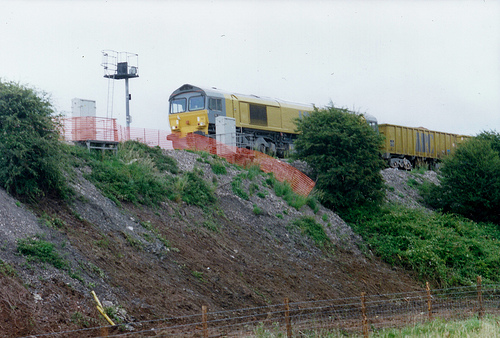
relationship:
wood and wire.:
[283, 295, 293, 337] [207, 301, 285, 338]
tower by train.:
[99, 47, 140, 143] [168, 82, 476, 174]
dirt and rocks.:
[0, 150, 497, 337] [0, 147, 496, 337]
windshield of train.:
[170, 93, 203, 114] [168, 82, 476, 174]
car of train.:
[376, 121, 479, 171] [168, 82, 476, 174]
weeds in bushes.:
[339, 202, 499, 291] [293, 102, 388, 220]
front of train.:
[168, 81, 226, 153] [168, 82, 476, 174]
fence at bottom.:
[26, 274, 500, 337] [1, 275, 500, 335]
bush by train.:
[293, 102, 388, 220] [168, 82, 476, 174]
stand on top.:
[99, 47, 140, 143] [101, 49, 140, 81]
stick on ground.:
[91, 289, 117, 327] [0, 150, 497, 337]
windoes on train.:
[170, 93, 203, 114] [168, 82, 476, 174]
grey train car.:
[168, 81, 226, 153] [168, 83, 381, 167]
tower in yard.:
[99, 47, 140, 143] [0, 82, 500, 336]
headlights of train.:
[170, 116, 208, 131] [168, 82, 476, 174]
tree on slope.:
[295, 107, 385, 219] [1, 143, 499, 337]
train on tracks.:
[168, 82, 476, 174] [271, 157, 455, 171]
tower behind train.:
[99, 47, 140, 143] [168, 82, 476, 174]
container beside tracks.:
[213, 116, 238, 159] [271, 157, 455, 171]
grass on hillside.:
[75, 142, 307, 215] [1, 143, 499, 337]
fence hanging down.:
[55, 115, 314, 198] [57, 115, 315, 201]